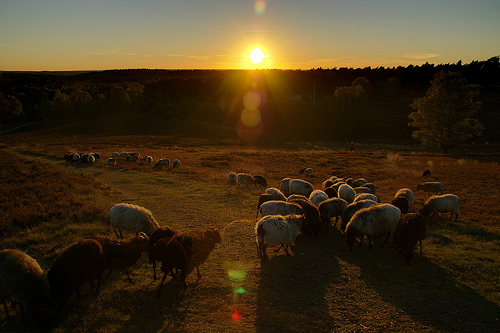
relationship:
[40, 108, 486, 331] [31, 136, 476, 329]
sheep in field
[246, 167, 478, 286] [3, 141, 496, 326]
sheep in field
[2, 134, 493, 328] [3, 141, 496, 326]
grass in field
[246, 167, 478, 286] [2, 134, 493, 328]
sheep eating grass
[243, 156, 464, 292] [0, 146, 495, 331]
sheep in pasture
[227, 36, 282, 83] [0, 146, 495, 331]
sun over pasture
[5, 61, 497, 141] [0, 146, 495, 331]
trees are surrounding pasture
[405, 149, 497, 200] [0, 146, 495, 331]
bush in pasture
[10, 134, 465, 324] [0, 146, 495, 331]
path in pasture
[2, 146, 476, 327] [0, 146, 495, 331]
sheep in pasture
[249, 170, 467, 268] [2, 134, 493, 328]
sheep in grass